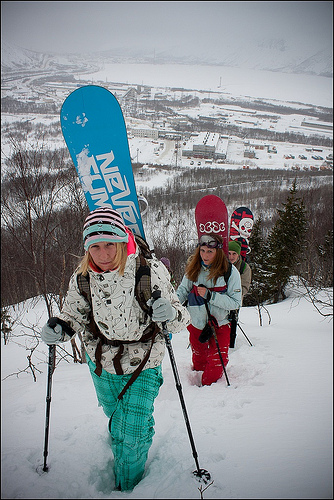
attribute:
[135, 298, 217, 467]
pole — ski pole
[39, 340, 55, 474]
pole — ski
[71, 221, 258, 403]
people — three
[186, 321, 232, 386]
snowpants — red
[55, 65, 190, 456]
snowboard — red 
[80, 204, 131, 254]
cap — stocking cap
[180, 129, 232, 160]
building — large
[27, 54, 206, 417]
snowboard — blue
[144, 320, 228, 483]
pole — snow shoe pole,  shoe pole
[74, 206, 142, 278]
hair — blonde